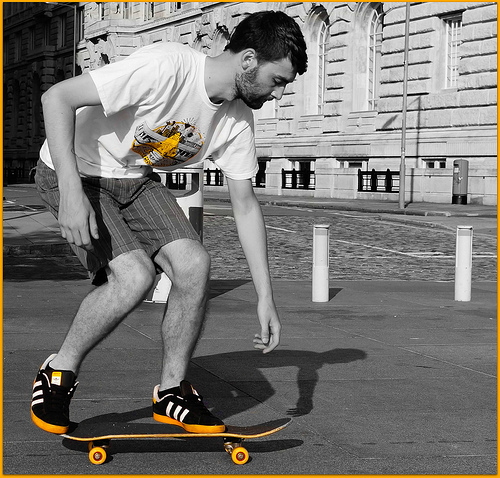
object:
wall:
[399, 120, 455, 185]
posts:
[310, 223, 474, 303]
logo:
[131, 117, 205, 169]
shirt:
[38, 40, 262, 181]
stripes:
[165, 401, 189, 423]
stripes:
[29, 380, 44, 407]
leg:
[125, 189, 212, 391]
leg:
[54, 197, 157, 370]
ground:
[356, 223, 405, 259]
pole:
[399, 1, 411, 211]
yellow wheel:
[88, 447, 107, 466]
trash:
[136, 160, 202, 303]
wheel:
[231, 446, 251, 467]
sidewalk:
[0, 276, 500, 478]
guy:
[31, 9, 310, 437]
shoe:
[152, 380, 227, 434]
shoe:
[30, 352, 79, 435]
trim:
[152, 413, 224, 434]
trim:
[29, 406, 69, 436]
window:
[346, 1, 384, 112]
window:
[429, 7, 463, 94]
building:
[0, 0, 498, 207]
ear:
[240, 48, 256, 69]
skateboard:
[56, 418, 293, 466]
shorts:
[34, 159, 201, 287]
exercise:
[38, 2, 303, 459]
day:
[0, 0, 500, 478]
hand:
[57, 191, 100, 253]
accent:
[28, 366, 293, 466]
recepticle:
[132, 167, 206, 299]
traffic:
[302, 200, 312, 207]